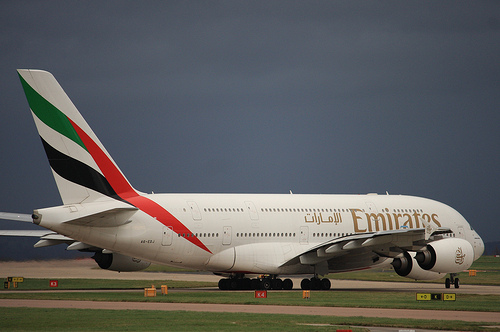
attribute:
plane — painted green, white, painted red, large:
[0, 67, 486, 292]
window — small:
[237, 233, 239, 235]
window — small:
[309, 210, 312, 213]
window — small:
[213, 208, 215, 210]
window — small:
[388, 209, 390, 212]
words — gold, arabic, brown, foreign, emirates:
[303, 209, 441, 233]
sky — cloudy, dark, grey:
[0, 3, 498, 253]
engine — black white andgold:
[410, 237, 472, 277]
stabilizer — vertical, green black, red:
[19, 68, 138, 226]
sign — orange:
[300, 290, 310, 297]